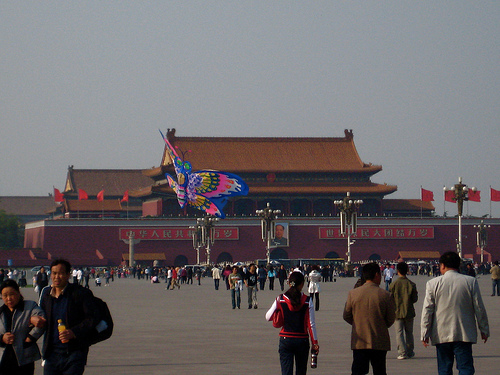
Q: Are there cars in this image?
A: No, there are no cars.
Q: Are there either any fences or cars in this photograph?
A: No, there are no cars or fences.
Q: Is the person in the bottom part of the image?
A: Yes, the person is in the bottom of the image.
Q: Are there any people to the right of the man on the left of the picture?
A: Yes, there is a person to the right of the man.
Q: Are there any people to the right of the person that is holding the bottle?
A: Yes, there is a person to the right of the man.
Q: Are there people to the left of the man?
A: No, the person is to the right of the man.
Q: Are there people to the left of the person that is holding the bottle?
A: No, the person is to the right of the man.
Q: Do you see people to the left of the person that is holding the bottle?
A: No, the person is to the right of the man.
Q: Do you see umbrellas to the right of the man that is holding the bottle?
A: No, there is a person to the right of the man.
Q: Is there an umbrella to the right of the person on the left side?
A: No, there is a person to the right of the man.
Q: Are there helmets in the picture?
A: No, there are no helmets.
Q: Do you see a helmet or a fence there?
A: No, there are no helmets or fences.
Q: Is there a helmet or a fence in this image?
A: No, there are no helmets or fences.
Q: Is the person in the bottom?
A: Yes, the person is in the bottom of the image.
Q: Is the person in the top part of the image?
A: No, the person is in the bottom of the image.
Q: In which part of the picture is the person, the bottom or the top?
A: The person is in the bottom of the image.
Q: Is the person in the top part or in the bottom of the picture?
A: The person is in the bottom of the image.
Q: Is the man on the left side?
A: Yes, the man is on the left of the image.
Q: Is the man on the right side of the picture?
A: No, the man is on the left of the image.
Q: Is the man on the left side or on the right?
A: The man is on the left of the image.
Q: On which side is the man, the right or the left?
A: The man is on the left of the image.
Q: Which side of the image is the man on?
A: The man is on the left of the image.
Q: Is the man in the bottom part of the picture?
A: Yes, the man is in the bottom of the image.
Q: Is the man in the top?
A: No, the man is in the bottom of the image.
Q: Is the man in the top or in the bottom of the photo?
A: The man is in the bottom of the image.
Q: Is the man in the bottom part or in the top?
A: The man is in the bottom of the image.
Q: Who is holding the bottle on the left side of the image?
A: The man is holding the bottle.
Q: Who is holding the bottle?
A: The man is holding the bottle.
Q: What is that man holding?
A: The man is holding the bottle.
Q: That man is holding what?
A: The man is holding the bottle.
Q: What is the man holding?
A: The man is holding the bottle.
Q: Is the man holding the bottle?
A: Yes, the man is holding the bottle.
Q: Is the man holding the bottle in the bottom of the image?
A: Yes, the man is holding the bottle.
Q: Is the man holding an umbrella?
A: No, the man is holding the bottle.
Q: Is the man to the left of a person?
A: Yes, the man is to the left of a person.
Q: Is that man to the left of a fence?
A: No, the man is to the left of a person.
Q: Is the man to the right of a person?
A: No, the man is to the left of a person.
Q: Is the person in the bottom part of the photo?
A: Yes, the person is in the bottom of the image.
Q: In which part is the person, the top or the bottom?
A: The person is in the bottom of the image.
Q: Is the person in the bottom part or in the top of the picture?
A: The person is in the bottom of the image.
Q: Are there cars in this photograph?
A: No, there are no cars.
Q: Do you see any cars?
A: No, there are no cars.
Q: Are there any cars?
A: No, there are no cars.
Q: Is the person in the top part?
A: No, the person is in the bottom of the image.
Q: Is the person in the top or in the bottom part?
A: The person is in the bottom of the image.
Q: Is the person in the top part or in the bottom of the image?
A: The person is in the bottom of the image.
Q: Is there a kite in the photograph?
A: Yes, there is a kite.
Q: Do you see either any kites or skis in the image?
A: Yes, there is a kite.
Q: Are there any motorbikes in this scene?
A: No, there are no motorbikes.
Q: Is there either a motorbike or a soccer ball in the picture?
A: No, there are no motorcycles or soccer balls.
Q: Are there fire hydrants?
A: No, there are no fire hydrants.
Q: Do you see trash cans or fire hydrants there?
A: No, there are no fire hydrants or trash cans.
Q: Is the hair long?
A: Yes, the hair is long.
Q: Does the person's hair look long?
A: Yes, the hair is long.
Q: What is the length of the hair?
A: The hair is long.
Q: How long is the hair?
A: The hair is long.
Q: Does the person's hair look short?
A: No, the hair is long.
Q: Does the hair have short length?
A: No, the hair is long.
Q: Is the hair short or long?
A: The hair is long.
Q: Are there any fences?
A: No, there are no fences.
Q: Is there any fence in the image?
A: No, there are no fences.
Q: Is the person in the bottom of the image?
A: Yes, the person is in the bottom of the image.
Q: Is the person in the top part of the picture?
A: No, the person is in the bottom of the image.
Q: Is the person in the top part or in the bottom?
A: The person is in the bottom of the image.